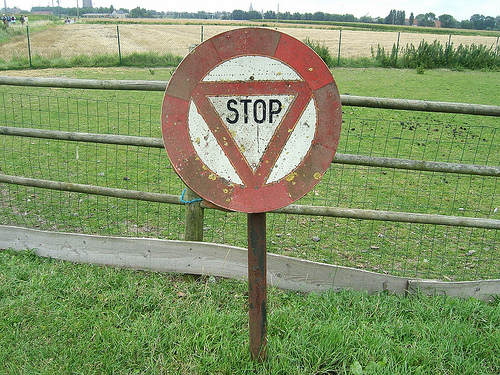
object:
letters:
[267, 98, 281, 125]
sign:
[161, 25, 342, 213]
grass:
[0, 68, 499, 284]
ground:
[0, 21, 499, 61]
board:
[0, 222, 499, 314]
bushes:
[367, 30, 401, 69]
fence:
[0, 75, 499, 305]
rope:
[178, 185, 199, 204]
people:
[19, 13, 26, 26]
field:
[0, 23, 138, 60]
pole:
[243, 210, 268, 357]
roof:
[26, 8, 56, 18]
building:
[28, 9, 64, 23]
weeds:
[94, 51, 119, 68]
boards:
[0, 173, 182, 203]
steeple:
[84, 0, 92, 3]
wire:
[0, 134, 182, 197]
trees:
[409, 11, 416, 26]